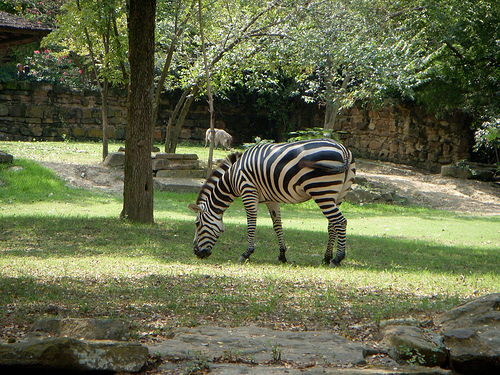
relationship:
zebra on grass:
[190, 148, 356, 268] [6, 258, 377, 345]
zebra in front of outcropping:
[190, 148, 356, 268] [154, 153, 202, 186]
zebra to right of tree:
[190, 148, 356, 268] [125, 1, 157, 222]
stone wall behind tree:
[3, 30, 102, 140] [125, 1, 157, 222]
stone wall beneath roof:
[3, 30, 102, 140] [0, 10, 54, 37]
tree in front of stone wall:
[125, 1, 157, 222] [3, 30, 102, 140]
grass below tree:
[6, 258, 377, 345] [125, 1, 157, 222]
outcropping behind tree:
[154, 153, 202, 186] [125, 1, 157, 222]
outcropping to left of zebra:
[154, 153, 202, 186] [190, 148, 356, 268]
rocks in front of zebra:
[174, 326, 362, 374] [190, 148, 356, 268]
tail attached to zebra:
[295, 160, 344, 171] [190, 148, 356, 268]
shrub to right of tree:
[421, 3, 498, 169] [125, 1, 157, 222]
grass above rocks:
[6, 258, 377, 345] [174, 326, 362, 374]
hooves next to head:
[244, 246, 347, 267] [194, 206, 224, 256]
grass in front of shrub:
[6, 258, 377, 345] [421, 3, 498, 169]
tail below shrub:
[295, 160, 344, 171] [421, 3, 498, 169]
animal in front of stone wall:
[207, 127, 233, 148] [3, 30, 102, 140]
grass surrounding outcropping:
[6, 258, 377, 345] [154, 153, 202, 186]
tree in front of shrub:
[125, 1, 157, 222] [421, 3, 498, 169]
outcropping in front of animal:
[154, 153, 202, 186] [207, 127, 233, 148]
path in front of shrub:
[359, 159, 499, 212] [421, 3, 498, 169]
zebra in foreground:
[190, 148, 356, 268] [0, 139, 495, 351]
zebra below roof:
[190, 148, 356, 268] [0, 10, 54, 37]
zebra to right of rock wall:
[190, 148, 356, 268] [347, 103, 471, 169]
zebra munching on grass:
[190, 148, 356, 268] [6, 258, 377, 345]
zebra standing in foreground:
[190, 148, 356, 268] [0, 139, 495, 351]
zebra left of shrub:
[190, 148, 356, 268] [421, 3, 498, 169]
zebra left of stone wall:
[190, 148, 356, 268] [3, 30, 102, 140]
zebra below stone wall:
[190, 148, 356, 268] [3, 30, 102, 140]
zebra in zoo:
[190, 148, 356, 268] [0, 0, 499, 374]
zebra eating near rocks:
[190, 148, 356, 268] [174, 326, 362, 374]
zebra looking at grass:
[190, 148, 356, 268] [6, 258, 377, 345]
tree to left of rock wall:
[125, 1, 157, 222] [347, 103, 471, 169]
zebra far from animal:
[190, 148, 356, 268] [207, 127, 233, 148]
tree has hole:
[125, 1, 157, 222] [141, 182, 151, 192]